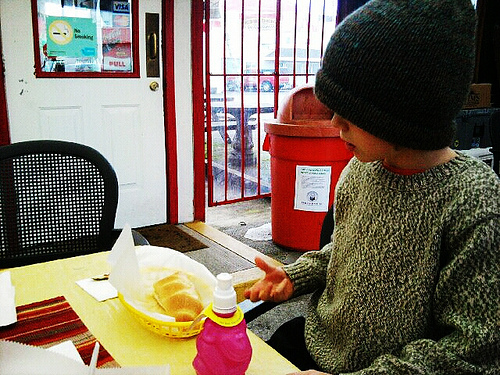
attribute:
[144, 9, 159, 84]
handle — on table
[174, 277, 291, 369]
bottle — on the table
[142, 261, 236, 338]
sandwich — on the table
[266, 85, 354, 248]
trash can — on the table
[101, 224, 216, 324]
paper — on the table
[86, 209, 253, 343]
basket — on table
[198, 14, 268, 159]
gate — red, metal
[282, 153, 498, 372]
sweater — on the boy, thick, grey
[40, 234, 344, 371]
table — on table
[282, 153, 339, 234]
label — white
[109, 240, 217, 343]
train — on table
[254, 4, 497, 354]
child — on table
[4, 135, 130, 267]
chair — on table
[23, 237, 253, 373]
table — on table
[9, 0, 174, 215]
door — on the table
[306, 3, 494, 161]
hat — on the boy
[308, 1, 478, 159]
hat — on table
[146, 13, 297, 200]
gate — on table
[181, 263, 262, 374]
container — on table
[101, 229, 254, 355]
basket — yellow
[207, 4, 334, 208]
bars — on the table